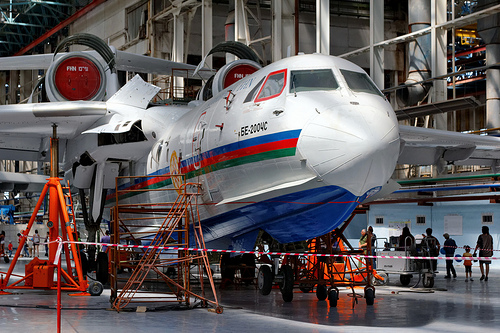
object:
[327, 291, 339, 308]
tires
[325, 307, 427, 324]
shadow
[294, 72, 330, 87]
windshield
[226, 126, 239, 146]
bars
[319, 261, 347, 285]
orange box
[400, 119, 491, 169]
motorcycle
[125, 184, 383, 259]
blue bottom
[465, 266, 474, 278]
white sock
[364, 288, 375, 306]
wheels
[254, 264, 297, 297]
front wheels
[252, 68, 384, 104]
cockpit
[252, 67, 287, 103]
red border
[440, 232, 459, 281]
people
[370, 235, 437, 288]
cart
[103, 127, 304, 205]
stripe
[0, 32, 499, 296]
airplane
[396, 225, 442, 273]
people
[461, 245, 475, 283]
kid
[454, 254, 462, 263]
balloon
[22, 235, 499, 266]
rope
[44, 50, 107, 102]
engine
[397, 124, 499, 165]
wing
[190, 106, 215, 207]
door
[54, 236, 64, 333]
pole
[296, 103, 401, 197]
plane nose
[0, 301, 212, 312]
black wires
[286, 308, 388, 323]
floor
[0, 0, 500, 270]
building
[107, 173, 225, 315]
case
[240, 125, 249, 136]
letters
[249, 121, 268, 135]
letter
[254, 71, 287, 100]
window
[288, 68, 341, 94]
window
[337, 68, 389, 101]
window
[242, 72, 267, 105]
window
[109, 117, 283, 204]
side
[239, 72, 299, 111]
window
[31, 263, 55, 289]
tip